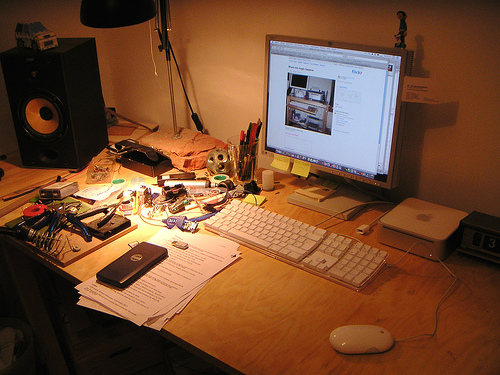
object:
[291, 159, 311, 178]
post-it note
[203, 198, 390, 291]
computer keyboard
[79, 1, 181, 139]
lamp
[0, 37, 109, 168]
speaker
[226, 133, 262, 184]
glass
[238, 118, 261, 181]
pencils pens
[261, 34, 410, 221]
computer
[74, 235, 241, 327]
papers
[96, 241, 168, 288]
phone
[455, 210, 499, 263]
clock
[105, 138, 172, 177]
stapler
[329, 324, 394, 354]
mouse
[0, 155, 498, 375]
desk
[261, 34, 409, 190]
computer monitor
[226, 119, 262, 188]
pens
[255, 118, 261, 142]
pencils